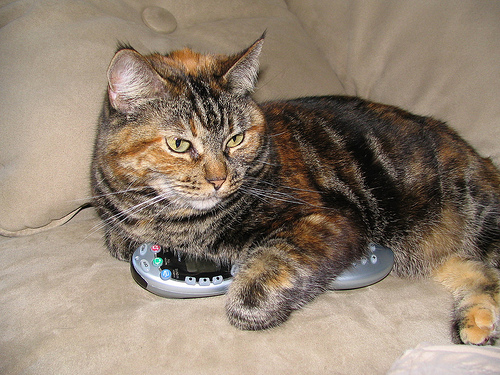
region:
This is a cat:
[79, 19, 490, 329]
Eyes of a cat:
[153, 112, 255, 165]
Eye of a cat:
[159, 127, 204, 162]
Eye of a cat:
[214, 119, 256, 159]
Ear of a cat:
[86, 37, 184, 119]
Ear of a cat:
[209, 19, 275, 101]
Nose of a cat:
[198, 163, 240, 194]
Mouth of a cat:
[180, 187, 233, 213]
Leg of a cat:
[220, 205, 379, 357]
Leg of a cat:
[442, 211, 498, 356]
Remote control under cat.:
[127, 242, 399, 290]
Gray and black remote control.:
[124, 237, 398, 294]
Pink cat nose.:
[207, 177, 224, 189]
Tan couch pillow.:
[0, 0, 345, 231]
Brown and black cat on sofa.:
[85, 44, 499, 339]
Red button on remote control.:
[152, 244, 159, 252]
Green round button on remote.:
[152, 257, 163, 264]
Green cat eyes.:
[164, 133, 242, 158]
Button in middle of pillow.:
[144, 6, 179, 33]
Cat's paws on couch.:
[457, 309, 497, 350]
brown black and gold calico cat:
[75, 39, 499, 351]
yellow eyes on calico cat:
[158, 125, 253, 157]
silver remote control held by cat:
[136, 229, 395, 312]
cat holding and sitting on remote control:
[87, 27, 498, 344]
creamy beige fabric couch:
[2, 4, 497, 361]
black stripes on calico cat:
[305, 105, 403, 227]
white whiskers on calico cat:
[78, 162, 323, 239]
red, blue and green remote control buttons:
[151, 238, 173, 283]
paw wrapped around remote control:
[217, 211, 352, 328]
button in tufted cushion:
[133, 4, 182, 38]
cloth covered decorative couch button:
[139, 5, 178, 34]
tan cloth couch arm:
[0, 0, 350, 240]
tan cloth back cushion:
[284, 0, 499, 172]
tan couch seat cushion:
[0, 204, 499, 374]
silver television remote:
[128, 238, 395, 301]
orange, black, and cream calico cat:
[86, 28, 498, 345]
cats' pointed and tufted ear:
[104, 38, 174, 113]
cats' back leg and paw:
[429, 255, 499, 343]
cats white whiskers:
[64, 177, 198, 247]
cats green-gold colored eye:
[162, 133, 192, 153]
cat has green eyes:
[162, 139, 247, 147]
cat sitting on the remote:
[109, 104, 496, 311]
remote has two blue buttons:
[147, 255, 179, 293]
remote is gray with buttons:
[132, 249, 392, 289]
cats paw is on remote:
[223, 226, 384, 331]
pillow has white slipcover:
[0, 102, 90, 231]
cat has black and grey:
[265, 111, 497, 242]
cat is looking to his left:
[98, 97, 255, 198]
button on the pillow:
[118, 0, 207, 41]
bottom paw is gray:
[263, 250, 348, 328]